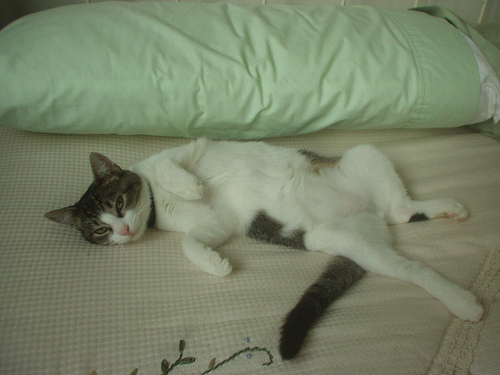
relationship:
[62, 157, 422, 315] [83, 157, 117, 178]
cat has ear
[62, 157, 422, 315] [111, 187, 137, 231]
cat has eye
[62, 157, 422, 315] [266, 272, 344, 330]
cat has tail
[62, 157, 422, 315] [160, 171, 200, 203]
cat has paw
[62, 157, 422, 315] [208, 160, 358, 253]
cat has belly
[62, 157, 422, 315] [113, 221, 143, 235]
cat has nose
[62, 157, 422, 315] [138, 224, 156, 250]
cat has mouth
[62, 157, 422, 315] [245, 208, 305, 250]
cat has spot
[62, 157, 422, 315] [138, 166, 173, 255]
cat wears collar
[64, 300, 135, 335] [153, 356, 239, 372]
blanket has stitch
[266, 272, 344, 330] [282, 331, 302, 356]
tail has tip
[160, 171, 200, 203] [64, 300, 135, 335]
paw on blanket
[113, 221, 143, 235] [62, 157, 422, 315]
nose of cat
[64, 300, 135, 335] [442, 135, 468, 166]
blanket has pattern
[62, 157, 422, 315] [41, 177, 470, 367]
cat in bed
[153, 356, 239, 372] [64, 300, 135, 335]
stitch on blanket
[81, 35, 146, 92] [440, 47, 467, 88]
pillow in case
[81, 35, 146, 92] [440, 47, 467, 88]
pillow out of case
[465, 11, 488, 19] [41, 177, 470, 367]
wall by bed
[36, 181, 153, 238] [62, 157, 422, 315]
head of cat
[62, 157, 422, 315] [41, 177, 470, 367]
cat on bed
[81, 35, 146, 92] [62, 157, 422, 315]
pillow behind cat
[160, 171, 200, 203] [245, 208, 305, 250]
paw has spot